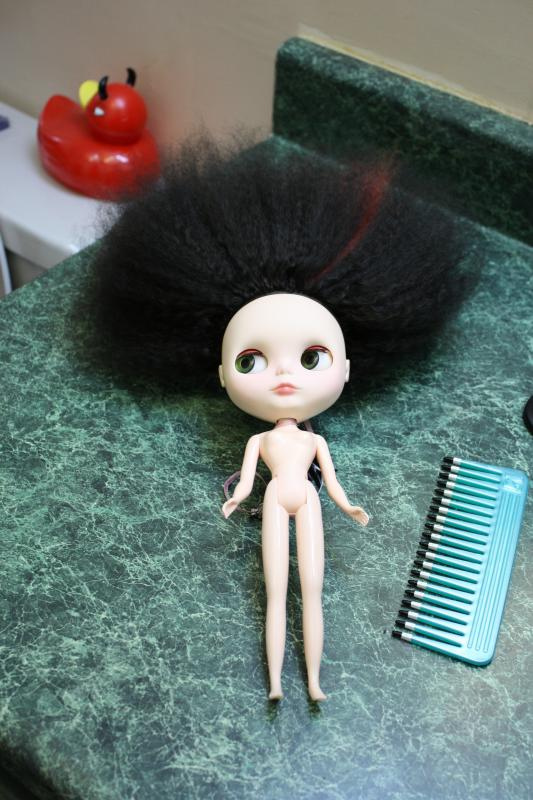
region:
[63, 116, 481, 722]
a doll with black hair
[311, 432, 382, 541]
left arm of a doll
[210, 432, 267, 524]
right arm of a doll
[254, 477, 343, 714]
the legs are long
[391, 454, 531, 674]
the comb is green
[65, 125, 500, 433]
the hair is black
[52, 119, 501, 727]
the doll is naked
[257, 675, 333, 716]
feet of the dall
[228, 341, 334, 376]
round eyes of the doll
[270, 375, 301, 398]
the mouth is pink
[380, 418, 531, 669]
a plastic comb on a counter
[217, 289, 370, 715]
a naked doll on a counter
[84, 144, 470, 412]
a doll with black hair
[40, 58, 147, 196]
a red rubber duck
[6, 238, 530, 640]
a green and black counter top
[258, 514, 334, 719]
a plastic dolls legs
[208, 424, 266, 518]
a plastic dolls arm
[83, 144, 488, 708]
a plastic doll with black hair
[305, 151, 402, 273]
a red streak in a dolls black hair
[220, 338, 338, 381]
a plastic dolls eyes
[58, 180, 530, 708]
doll laying on counter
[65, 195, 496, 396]
doll has a lot of hair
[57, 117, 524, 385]
dolls hair is black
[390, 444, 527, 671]
comb sitting on table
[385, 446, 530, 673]
comb on table is green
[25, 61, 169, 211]
rubber duck on tank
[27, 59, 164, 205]
rubber duck is red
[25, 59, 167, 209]
rubber duck looks mean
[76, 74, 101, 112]
duck's beak is yellow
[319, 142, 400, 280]
red streak in hair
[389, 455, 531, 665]
A blue comb with multiple teeth.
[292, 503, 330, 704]
The left leg of a white doll.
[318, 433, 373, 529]
The left white arm of a creepy doll.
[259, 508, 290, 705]
The right leg of a white doll.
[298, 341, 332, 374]
The left eye of a doll.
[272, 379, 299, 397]
The pink lips of a small doll.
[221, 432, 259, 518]
The right arm of a little female doll.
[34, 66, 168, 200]
A small red rubber duck with demonic horns.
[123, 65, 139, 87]
The left horn of a demon duck.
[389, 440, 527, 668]
Comb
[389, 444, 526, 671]
Light blue comb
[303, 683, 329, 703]
Right foot of a doll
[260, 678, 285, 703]
Left foot of a doll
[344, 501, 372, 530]
Right hand of a doll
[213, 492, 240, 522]
Left hand of a doll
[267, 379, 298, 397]
Mouth of a doll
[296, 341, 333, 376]
Right eye of a doll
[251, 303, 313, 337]
Forehead of a doll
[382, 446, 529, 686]
blue wide tooth comb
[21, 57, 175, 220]
red rubber duck with horns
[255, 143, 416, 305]
red streak in toy's hair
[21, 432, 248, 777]
green marbled counter top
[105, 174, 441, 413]
A doll with crazy hair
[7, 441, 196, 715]
A marble countertop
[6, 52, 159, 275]
A red duck with horns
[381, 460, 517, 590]
A blue and black brush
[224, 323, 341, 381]
A doll with green eyes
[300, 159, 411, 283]
A doll was red in its hair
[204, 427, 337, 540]
Something purple under the doll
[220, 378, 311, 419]
a doll with red lips